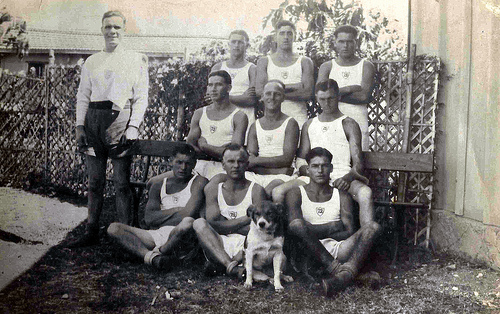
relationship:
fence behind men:
[5, 49, 446, 250] [70, 4, 410, 294]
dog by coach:
[246, 204, 291, 286] [72, 9, 149, 245]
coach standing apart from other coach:
[72, 9, 149, 245] [72, 9, 149, 245]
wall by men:
[407, 2, 498, 264] [62, 12, 380, 293]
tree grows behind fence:
[265, 0, 407, 51] [5, 49, 446, 250]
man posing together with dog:
[104, 144, 208, 269] [198, 195, 334, 289]